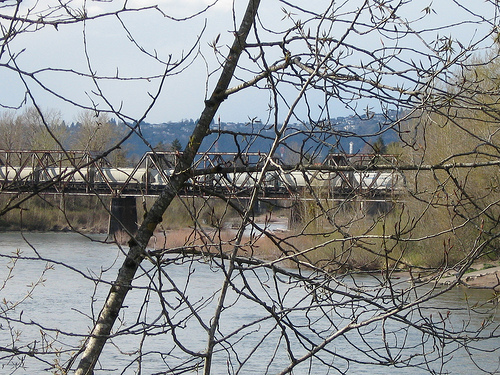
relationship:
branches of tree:
[129, 80, 432, 347] [11, 9, 349, 374]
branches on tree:
[8, 28, 479, 363] [22, 28, 431, 371]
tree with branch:
[11, 9, 349, 374] [176, 228, 452, 363]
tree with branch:
[11, 9, 349, 374] [179, 224, 396, 334]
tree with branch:
[11, 9, 349, 374] [242, 29, 369, 108]